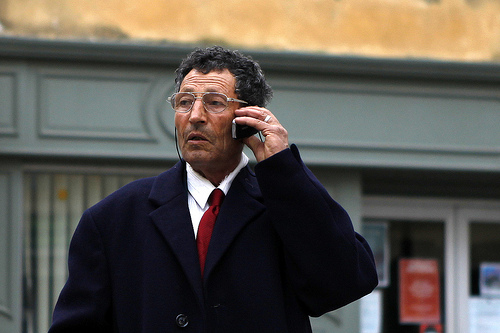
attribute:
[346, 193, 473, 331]
door — white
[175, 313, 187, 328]
button — top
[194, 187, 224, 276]
tie — red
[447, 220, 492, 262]
glassdoor — small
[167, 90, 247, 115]
glasses — pair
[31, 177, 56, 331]
white valence — window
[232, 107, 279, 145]
phone — cell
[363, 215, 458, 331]
door — glass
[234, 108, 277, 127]
finger — man's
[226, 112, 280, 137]
finger — man's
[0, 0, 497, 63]
wood work — light brown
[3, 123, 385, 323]
coat — navy blue, wool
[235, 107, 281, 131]
finger — man's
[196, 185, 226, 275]
tie — dark, red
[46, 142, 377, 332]
coat — dark blue, wool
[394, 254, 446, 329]
sign — white, red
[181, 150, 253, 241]
shirt — white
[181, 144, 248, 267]
dress shirt — white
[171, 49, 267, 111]
hair — dark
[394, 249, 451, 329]
sign — red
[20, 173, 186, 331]
valence — window, white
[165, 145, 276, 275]
shirt — white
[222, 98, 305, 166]
hand — man's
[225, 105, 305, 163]
hand — man's